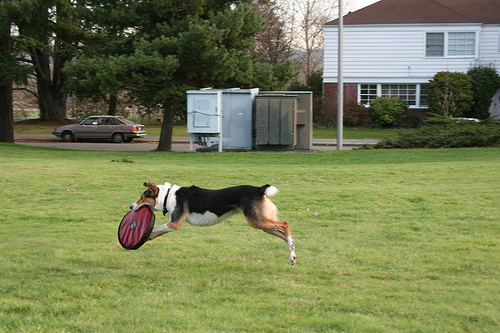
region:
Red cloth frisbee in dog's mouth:
[112, 195, 165, 240]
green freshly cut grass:
[316, 170, 486, 316]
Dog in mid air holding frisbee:
[138, 176, 347, 267]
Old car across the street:
[38, 84, 150, 153]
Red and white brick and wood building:
[321, 4, 483, 101]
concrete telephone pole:
[330, 4, 350, 156]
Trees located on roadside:
[66, 10, 299, 156]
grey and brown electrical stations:
[196, 88, 320, 156]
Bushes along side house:
[413, 67, 498, 124]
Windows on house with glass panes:
[431, 33, 475, 59]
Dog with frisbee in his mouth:
[118, 178, 300, 265]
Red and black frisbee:
[115, 206, 157, 249]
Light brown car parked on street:
[51, 111, 147, 143]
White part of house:
[322, 23, 498, 83]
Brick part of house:
[325, 81, 358, 123]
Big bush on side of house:
[423, 69, 477, 121]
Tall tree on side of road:
[65, 3, 257, 150]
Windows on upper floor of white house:
[421, 27, 478, 58]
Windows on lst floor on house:
[356, 82, 434, 109]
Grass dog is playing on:
[1, 142, 497, 331]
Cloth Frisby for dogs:
[114, 198, 163, 248]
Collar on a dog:
[161, 182, 171, 214]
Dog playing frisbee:
[120, 171, 301, 279]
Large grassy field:
[322, 157, 480, 324]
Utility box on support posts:
[185, 86, 227, 156]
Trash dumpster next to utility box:
[219, 83, 259, 153]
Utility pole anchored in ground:
[335, 0, 350, 152]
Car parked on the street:
[51, 105, 146, 147]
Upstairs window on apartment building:
[424, 26, 477, 64]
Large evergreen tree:
[75, 8, 270, 160]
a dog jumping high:
[77, 160, 322, 290]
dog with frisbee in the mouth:
[75, 167, 175, 251]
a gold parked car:
[40, 101, 145, 141]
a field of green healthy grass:
[310, 160, 456, 312]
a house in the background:
[324, 7, 498, 144]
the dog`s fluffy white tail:
[245, 173, 284, 208]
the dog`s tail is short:
[215, 159, 287, 217]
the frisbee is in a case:
[95, 195, 167, 262]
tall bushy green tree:
[56, 0, 309, 143]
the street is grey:
[26, 130, 149, 155]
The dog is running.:
[99, 170, 334, 272]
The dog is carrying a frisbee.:
[97, 175, 303, 277]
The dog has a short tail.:
[95, 172, 305, 274]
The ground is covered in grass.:
[327, 208, 470, 315]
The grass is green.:
[331, 217, 489, 321]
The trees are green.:
[2, 1, 252, 81]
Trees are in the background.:
[85, 4, 277, 149]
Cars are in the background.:
[43, 98, 160, 166]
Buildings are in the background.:
[312, 0, 497, 143]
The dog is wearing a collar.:
[153, 180, 178, 226]